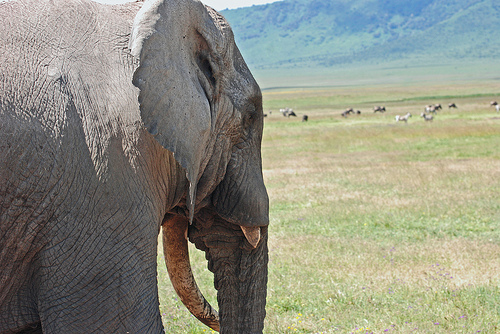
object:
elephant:
[1, 0, 269, 334]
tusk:
[240, 226, 260, 248]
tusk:
[161, 215, 220, 332]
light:
[2, 2, 129, 83]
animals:
[263, 100, 499, 126]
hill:
[220, 1, 499, 71]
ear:
[129, 0, 222, 225]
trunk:
[183, 219, 268, 333]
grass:
[279, 164, 500, 334]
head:
[150, 0, 271, 222]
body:
[2, 2, 142, 334]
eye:
[248, 114, 254, 120]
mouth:
[181, 206, 218, 227]